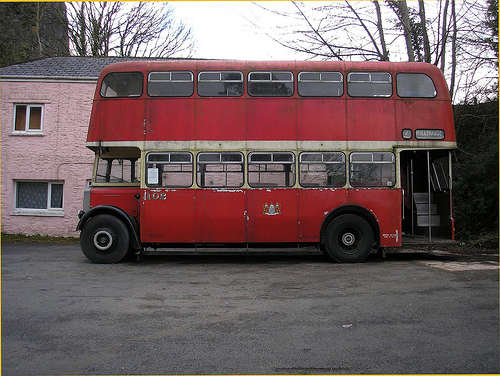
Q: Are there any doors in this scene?
A: Yes, there is a door.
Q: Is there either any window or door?
A: Yes, there is a door.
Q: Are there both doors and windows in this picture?
A: Yes, there are both a door and a window.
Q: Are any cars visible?
A: No, there are no cars.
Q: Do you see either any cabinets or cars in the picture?
A: No, there are no cars or cabinets.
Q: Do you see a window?
A: Yes, there is a window.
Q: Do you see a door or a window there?
A: Yes, there is a window.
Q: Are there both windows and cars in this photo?
A: No, there is a window but no cars.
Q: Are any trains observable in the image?
A: No, there are no trains.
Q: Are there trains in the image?
A: No, there are no trains.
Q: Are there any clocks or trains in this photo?
A: No, there are no trains or clocks.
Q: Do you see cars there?
A: No, there are no cars.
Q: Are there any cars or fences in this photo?
A: No, there are no cars or fences.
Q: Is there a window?
A: Yes, there is a window.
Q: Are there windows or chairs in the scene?
A: Yes, there is a window.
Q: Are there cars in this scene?
A: No, there are no cars.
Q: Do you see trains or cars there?
A: No, there are no cars or trains.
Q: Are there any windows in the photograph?
A: Yes, there is a window.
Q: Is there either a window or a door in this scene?
A: Yes, there is a window.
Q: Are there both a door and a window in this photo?
A: Yes, there are both a window and a door.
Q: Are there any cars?
A: No, there are no cars.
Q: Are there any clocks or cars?
A: No, there are no cars or clocks.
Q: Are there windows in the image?
A: Yes, there is a window.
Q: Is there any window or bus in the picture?
A: Yes, there is a window.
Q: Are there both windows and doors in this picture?
A: Yes, there are both a window and a door.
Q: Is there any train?
A: No, there are no trains.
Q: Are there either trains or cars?
A: No, there are no trains or cars.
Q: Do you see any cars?
A: No, there are no cars.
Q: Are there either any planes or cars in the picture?
A: No, there are no cars or planes.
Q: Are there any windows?
A: Yes, there are windows.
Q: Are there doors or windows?
A: Yes, there are windows.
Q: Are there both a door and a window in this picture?
A: Yes, there are both a window and a door.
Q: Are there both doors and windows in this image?
A: Yes, there are both windows and a door.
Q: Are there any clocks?
A: No, there are no clocks.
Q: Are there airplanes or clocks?
A: No, there are no clocks or airplanes.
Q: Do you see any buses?
A: Yes, there is a bus.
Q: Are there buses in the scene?
A: Yes, there is a bus.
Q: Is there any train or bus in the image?
A: Yes, there is a bus.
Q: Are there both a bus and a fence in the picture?
A: No, there is a bus but no fences.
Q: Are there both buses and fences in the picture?
A: No, there is a bus but no fences.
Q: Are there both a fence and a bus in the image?
A: No, there is a bus but no fences.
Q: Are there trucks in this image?
A: No, there are no trucks.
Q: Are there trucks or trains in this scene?
A: No, there are no trucks or trains.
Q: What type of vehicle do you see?
A: The vehicle is a bus.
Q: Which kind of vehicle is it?
A: The vehicle is a bus.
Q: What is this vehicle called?
A: This is a bus.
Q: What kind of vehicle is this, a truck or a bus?
A: This is a bus.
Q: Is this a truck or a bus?
A: This is a bus.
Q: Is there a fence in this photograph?
A: No, there are no fences.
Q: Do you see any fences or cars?
A: No, there are no fences or cars.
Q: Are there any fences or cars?
A: No, there are no fences or cars.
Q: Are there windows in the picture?
A: Yes, there are windows.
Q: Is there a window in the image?
A: Yes, there are windows.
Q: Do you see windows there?
A: Yes, there are windows.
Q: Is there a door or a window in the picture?
A: Yes, there are windows.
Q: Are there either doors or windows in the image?
A: Yes, there are windows.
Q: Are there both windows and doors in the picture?
A: Yes, there are both windows and a door.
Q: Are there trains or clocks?
A: No, there are no trains or clocks.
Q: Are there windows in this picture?
A: Yes, there is a window.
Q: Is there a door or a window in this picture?
A: Yes, there is a window.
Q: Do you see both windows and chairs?
A: No, there is a window but no chairs.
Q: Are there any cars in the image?
A: No, there are no cars.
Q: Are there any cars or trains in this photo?
A: No, there are no cars or trains.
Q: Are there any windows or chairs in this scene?
A: Yes, there is a window.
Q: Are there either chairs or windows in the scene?
A: Yes, there is a window.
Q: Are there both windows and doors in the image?
A: Yes, there are both a window and a door.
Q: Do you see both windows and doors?
A: Yes, there are both a window and a door.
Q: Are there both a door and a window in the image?
A: Yes, there are both a window and a door.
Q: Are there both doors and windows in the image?
A: Yes, there are both a window and a door.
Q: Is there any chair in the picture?
A: No, there are no chairs.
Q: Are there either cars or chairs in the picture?
A: No, there are no chairs or cars.